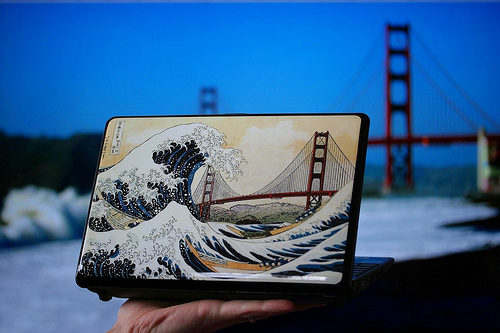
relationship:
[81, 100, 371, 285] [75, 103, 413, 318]
image on laptop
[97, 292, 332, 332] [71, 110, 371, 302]
hand holding computer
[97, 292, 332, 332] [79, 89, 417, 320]
hand holding painting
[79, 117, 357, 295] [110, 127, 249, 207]
painting of wave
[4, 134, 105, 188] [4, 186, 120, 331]
cliffside above water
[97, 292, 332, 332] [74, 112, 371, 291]
hand holding picture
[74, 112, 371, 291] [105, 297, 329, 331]
picture in a hand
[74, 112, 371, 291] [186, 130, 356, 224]
picture of a bridge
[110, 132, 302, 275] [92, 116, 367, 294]
ocean waves in image